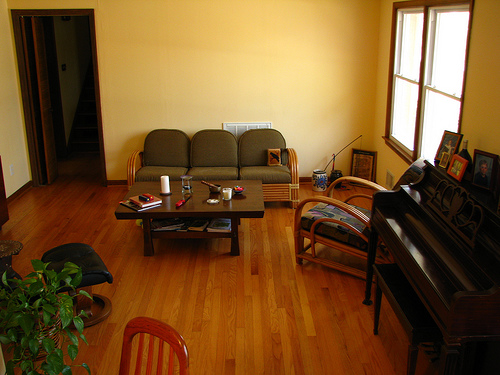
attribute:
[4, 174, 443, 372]
floor — wooden, brown, clean, hardwood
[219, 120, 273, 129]
vent — white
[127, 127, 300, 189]
couch — brown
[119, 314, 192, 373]
chair — wooden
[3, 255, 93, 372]
plant — green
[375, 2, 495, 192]
wall — yellow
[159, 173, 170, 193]
candle — white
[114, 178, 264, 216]
table — black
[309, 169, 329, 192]
vase — blue, white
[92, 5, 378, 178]
wall — yellow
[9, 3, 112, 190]
door — open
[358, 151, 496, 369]
piano — wood, dark brown, wooden, brown, black 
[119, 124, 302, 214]
couch — green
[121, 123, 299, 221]
couch — green, small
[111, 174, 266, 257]
table — brown, coffee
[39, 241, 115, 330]
seat — black, leather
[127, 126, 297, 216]
couch — brown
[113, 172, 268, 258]
coffee table — wooden, brown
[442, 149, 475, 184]
photo frame — red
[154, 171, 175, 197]
candle — white, wax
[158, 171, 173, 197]
candle — tall, white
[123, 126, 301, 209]
couch — brown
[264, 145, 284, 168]
pillow — brown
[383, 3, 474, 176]
window — large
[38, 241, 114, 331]
foot stool — blue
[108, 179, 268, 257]
coffee table — brown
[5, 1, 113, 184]
door frame — brown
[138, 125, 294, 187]
cushions — green 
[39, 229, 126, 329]
ottoman — Leather 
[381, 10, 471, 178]
window — Wooden 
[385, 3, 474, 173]
frame — brown 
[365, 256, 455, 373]
piano bench — brown , Dark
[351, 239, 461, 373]
piano bench — wood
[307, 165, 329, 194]
jar — white , Blue , decorative 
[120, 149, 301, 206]
trim — wooden 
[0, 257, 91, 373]
vine plant — small , green 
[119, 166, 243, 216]
objects — different 